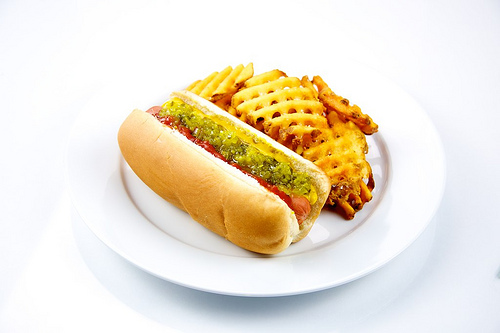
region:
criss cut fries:
[238, 53, 375, 167]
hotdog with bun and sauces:
[125, 111, 306, 256]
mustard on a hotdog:
[168, 104, 309, 207]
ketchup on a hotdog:
[165, 92, 305, 228]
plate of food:
[27, 14, 367, 331]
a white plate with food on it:
[64, 40, 489, 316]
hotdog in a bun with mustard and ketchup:
[139, 80, 326, 277]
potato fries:
[212, 35, 394, 183]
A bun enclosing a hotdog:
[131, 98, 324, 248]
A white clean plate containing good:
[22, 38, 434, 328]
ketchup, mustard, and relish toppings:
[153, 96, 328, 203]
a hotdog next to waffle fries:
[101, 66, 382, 256]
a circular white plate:
[59, 61, 471, 306]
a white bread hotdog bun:
[112, 107, 294, 252]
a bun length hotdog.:
[123, 84, 317, 239]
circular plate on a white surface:
[26, 23, 466, 318]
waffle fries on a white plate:
[205, 39, 464, 226]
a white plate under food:
[65, 52, 457, 313]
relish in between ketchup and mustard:
[153, 97, 332, 224]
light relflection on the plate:
[295, 150, 457, 267]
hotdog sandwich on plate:
[122, 54, 309, 308]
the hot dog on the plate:
[118, 87, 322, 252]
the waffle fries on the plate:
[193, 62, 377, 207]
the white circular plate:
[66, 50, 448, 297]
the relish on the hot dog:
[172, 107, 204, 127]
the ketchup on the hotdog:
[181, 129, 194, 142]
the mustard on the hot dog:
[225, 125, 242, 137]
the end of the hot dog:
[292, 197, 311, 222]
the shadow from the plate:
[171, 290, 328, 318]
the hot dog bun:
[121, 102, 332, 250]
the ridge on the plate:
[133, 207, 180, 250]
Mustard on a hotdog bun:
[211, 114, 242, 133]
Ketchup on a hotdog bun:
[192, 140, 216, 153]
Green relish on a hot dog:
[183, 113, 313, 195]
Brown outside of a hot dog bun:
[121, 118, 281, 250]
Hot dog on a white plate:
[116, 97, 328, 254]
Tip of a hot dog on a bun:
[293, 195, 311, 227]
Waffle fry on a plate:
[303, 126, 373, 204]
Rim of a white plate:
[185, 247, 327, 297]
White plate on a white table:
[413, 82, 497, 294]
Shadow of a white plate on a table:
[184, 292, 360, 324]